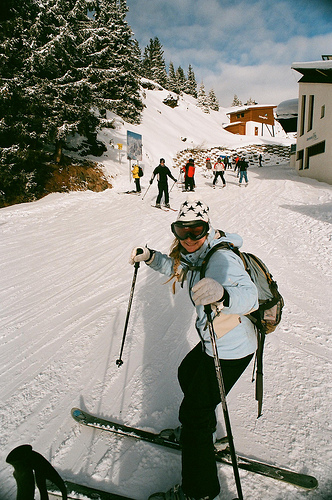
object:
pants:
[156, 181, 169, 205]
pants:
[239, 171, 249, 183]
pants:
[213, 171, 226, 185]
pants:
[135, 178, 141, 193]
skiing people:
[205, 157, 213, 180]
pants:
[177, 340, 255, 500]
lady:
[127, 200, 261, 498]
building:
[288, 55, 332, 185]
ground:
[0, 173, 332, 499]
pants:
[185, 177, 194, 190]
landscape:
[113, 8, 305, 191]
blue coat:
[144, 228, 261, 361]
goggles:
[171, 219, 210, 241]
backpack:
[240, 252, 285, 336]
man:
[149, 158, 177, 209]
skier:
[181, 159, 196, 192]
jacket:
[181, 163, 195, 178]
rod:
[116, 247, 143, 368]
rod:
[204, 302, 244, 498]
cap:
[177, 199, 212, 226]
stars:
[186, 205, 196, 213]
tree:
[150, 36, 167, 89]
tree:
[40, 0, 82, 164]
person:
[130, 163, 144, 190]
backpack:
[138, 166, 144, 178]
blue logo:
[73, 409, 82, 418]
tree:
[0, 0, 70, 202]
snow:
[9, 256, 91, 379]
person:
[149, 158, 178, 209]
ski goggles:
[170, 219, 209, 241]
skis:
[70, 406, 319, 488]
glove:
[191, 277, 229, 307]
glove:
[128, 245, 155, 265]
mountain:
[75, 22, 296, 177]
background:
[1, 0, 330, 206]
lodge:
[222, 104, 277, 137]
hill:
[0, 72, 289, 192]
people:
[212, 157, 227, 188]